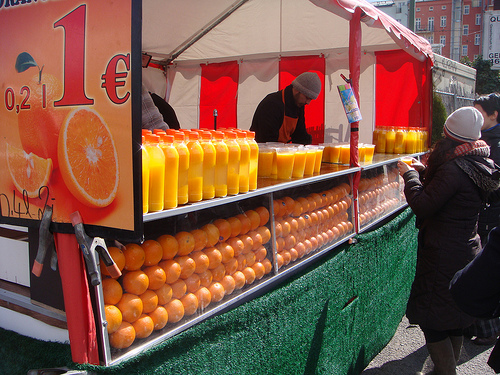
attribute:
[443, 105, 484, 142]
cap — white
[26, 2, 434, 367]
booth — white, red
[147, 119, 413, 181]
orange juice — fresh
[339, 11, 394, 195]
stand — metal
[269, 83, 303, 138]
apron — red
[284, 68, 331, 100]
cap — grey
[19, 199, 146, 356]
clamps — metal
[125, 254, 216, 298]
orange — half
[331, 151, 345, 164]
orange — slice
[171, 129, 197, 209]
juice — orange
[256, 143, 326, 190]
juice — orange